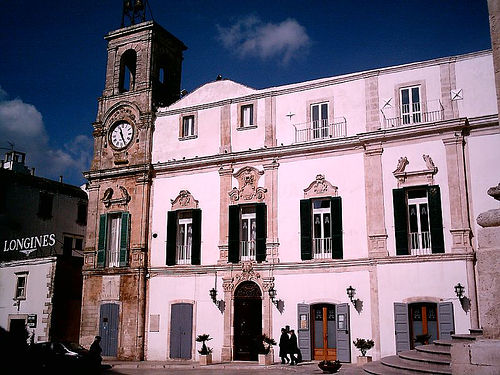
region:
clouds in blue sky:
[2, 1, 490, 186]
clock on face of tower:
[81, 22, 185, 363]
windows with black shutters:
[165, 185, 444, 268]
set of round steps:
[365, 328, 482, 373]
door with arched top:
[230, 278, 264, 361]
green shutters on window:
[96, 210, 130, 268]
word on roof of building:
[3, 233, 80, 342]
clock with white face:
[109, 119, 134, 149]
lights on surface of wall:
[208, 282, 468, 311]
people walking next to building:
[276, 325, 301, 365]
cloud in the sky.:
[233, 20, 295, 52]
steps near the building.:
[421, 345, 443, 366]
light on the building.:
[340, 280, 352, 300]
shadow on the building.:
[355, 301, 363, 315]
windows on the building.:
[411, 203, 426, 228]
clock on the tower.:
[109, 123, 131, 145]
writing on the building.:
[0, 233, 55, 250]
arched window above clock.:
[112, 47, 138, 89]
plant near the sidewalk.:
[197, 327, 212, 362]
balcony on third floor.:
[382, 105, 439, 127]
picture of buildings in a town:
[18, 18, 492, 371]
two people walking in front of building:
[275, 313, 358, 373]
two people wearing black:
[266, 313, 333, 373]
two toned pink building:
[124, 55, 489, 357]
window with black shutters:
[293, 172, 389, 278]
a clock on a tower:
[83, 7, 168, 364]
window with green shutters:
[75, 194, 180, 322]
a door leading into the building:
[196, 251, 346, 374]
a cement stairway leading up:
[337, 184, 496, 374]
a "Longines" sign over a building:
[4, 232, 66, 265]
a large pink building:
[158, 90, 484, 352]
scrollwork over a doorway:
[217, 258, 277, 295]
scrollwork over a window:
[218, 165, 274, 206]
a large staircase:
[357, 325, 491, 370]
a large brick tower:
[75, 19, 176, 356]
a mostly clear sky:
[20, 23, 491, 131]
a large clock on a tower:
[103, 103, 143, 156]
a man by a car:
[84, 335, 109, 374]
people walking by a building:
[268, 325, 318, 369]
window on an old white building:
[174, 216, 197, 265]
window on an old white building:
[238, 212, 258, 263]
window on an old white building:
[310, 198, 333, 260]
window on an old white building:
[404, 194, 431, 258]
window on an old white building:
[400, 83, 421, 127]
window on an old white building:
[311, 100, 328, 143]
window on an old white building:
[239, 102, 255, 128]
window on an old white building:
[179, 112, 194, 139]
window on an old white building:
[104, 212, 120, 270]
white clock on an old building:
[107, 119, 135, 151]